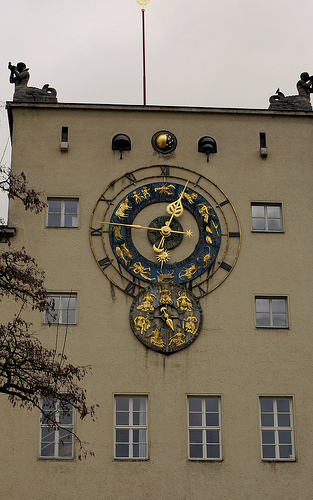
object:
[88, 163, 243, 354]
clock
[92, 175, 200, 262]
hands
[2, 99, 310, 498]
building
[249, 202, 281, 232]
window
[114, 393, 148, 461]
window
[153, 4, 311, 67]
sky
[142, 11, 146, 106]
rod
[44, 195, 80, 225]
window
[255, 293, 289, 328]
window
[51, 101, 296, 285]
building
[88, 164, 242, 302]
clock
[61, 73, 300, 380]
building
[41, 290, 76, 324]
window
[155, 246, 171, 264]
sun figure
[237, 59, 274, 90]
ground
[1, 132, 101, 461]
tree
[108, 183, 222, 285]
zodiac sign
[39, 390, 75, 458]
window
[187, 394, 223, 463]
window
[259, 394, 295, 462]
window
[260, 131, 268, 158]
buttress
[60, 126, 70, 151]
buttress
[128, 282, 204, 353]
mythological figures